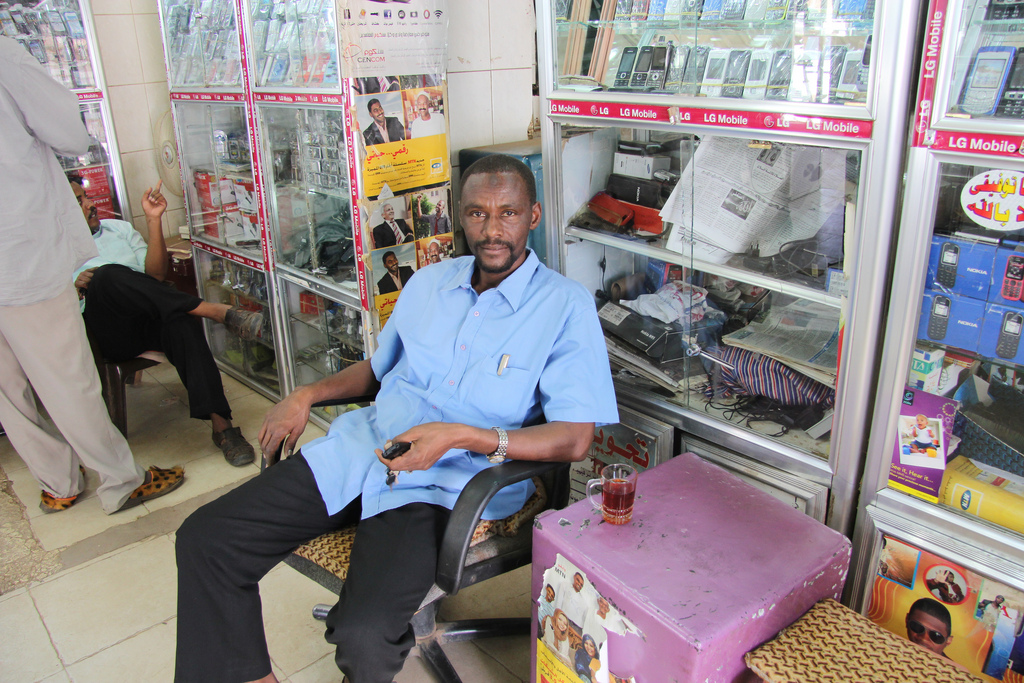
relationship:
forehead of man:
[460, 164, 534, 207] [164, 149, 630, 680]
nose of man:
[484, 212, 507, 239] [451, 149, 541, 274]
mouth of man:
[476, 234, 516, 261] [164, 149, 630, 680]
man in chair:
[344, 174, 572, 532] [275, 352, 548, 550]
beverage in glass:
[600, 475, 638, 520] [579, 463, 641, 524]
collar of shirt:
[436, 251, 541, 315] [294, 246, 623, 521]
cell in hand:
[369, 440, 417, 463] [375, 408, 465, 482]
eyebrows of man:
[455, 202, 523, 218] [75, 147, 629, 679]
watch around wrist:
[477, 413, 529, 470] [410, 336, 570, 564]